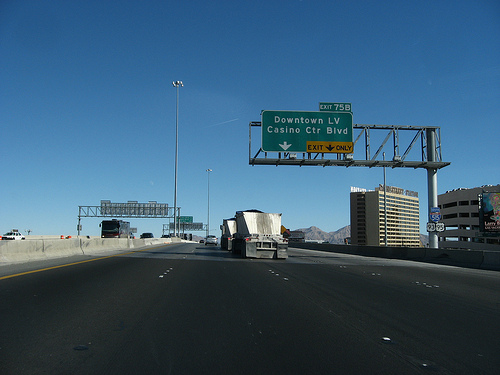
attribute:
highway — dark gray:
[1, 239, 496, 374]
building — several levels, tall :
[344, 179, 429, 254]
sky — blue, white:
[1, 0, 495, 254]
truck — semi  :
[221, 204, 291, 261]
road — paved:
[84, 265, 424, 350]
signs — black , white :
[424, 221, 453, 233]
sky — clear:
[13, 13, 498, 244]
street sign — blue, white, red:
[428, 208, 443, 223]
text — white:
[265, 127, 300, 132]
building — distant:
[348, 182, 421, 247]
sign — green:
[259, 98, 354, 156]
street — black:
[33, 182, 450, 332]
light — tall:
[123, 49, 335, 188]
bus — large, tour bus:
[96, 215, 135, 240]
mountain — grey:
[291, 223, 330, 242]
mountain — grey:
[325, 222, 350, 244]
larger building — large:
[345, 182, 427, 254]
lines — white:
[153, 261, 175, 285]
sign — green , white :
[255, 90, 382, 169]